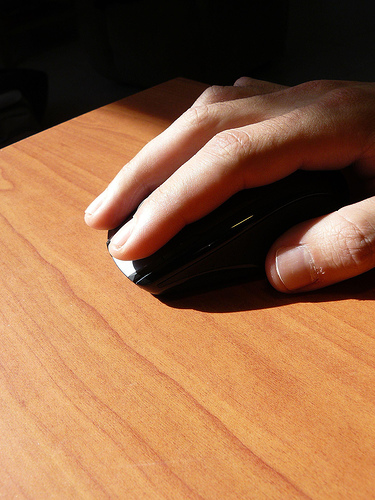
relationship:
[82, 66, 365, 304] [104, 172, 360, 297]
hand holding mouse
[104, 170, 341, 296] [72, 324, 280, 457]
computer mouse on table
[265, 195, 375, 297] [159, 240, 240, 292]
fingers on side of mouse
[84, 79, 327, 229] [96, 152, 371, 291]
finger on mouse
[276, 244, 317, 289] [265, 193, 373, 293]
finger nail on thumb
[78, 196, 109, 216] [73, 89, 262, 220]
finger nail on finger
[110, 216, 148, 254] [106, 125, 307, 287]
finger nail on finger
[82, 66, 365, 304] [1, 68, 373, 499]
hand resting on table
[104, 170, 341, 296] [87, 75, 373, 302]
computer mouse on table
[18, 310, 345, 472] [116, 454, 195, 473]
table has scratch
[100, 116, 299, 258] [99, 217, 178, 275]
finger on clickers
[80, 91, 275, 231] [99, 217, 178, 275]
finger on clickers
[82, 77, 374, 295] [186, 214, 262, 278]
hand holding computer mouse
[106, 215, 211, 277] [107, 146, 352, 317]
button of mouse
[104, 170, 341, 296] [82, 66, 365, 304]
computer mouse under hand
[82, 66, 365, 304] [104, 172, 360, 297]
hand controlling mouse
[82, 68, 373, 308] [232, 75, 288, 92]
person has finger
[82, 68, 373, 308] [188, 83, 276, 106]
person has finger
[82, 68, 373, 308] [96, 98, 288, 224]
person has finger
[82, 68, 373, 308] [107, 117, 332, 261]
person has finger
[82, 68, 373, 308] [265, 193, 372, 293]
person has finger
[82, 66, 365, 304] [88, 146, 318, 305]
hand on mouse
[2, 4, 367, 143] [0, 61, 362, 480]
dark room behind desk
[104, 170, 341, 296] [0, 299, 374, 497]
computer mouse on desk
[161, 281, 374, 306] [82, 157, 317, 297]
shadow of mouse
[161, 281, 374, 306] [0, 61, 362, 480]
shadow on desk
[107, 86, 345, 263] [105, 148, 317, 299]
finger on mouse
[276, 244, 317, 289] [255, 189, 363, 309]
finger nail on thumb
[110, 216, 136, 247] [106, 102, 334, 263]
finger nail on finger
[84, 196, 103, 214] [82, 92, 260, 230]
finger nail on finger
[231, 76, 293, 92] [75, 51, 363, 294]
finger on hand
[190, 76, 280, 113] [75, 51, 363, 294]
finger on hand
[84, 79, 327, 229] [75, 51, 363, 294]
finger on hand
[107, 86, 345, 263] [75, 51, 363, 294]
finger on hand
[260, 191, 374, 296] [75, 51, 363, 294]
fingers on hand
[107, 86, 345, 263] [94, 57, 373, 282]
finger attached to hand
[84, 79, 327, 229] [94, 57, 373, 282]
finger attached to hand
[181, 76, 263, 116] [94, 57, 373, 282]
finger attached to hand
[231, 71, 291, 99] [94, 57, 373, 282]
finger attached to hand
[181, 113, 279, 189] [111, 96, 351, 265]
knuckle on finger